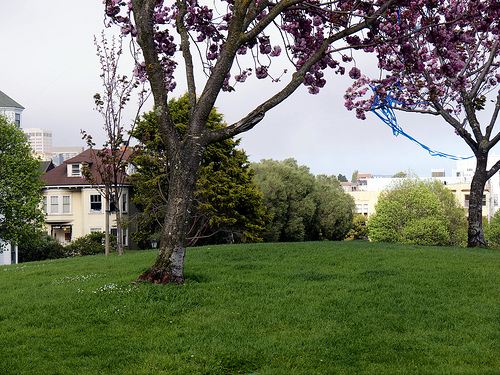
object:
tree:
[113, 86, 277, 248]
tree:
[74, 28, 159, 257]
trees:
[234, 156, 357, 244]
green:
[287, 189, 320, 218]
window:
[88, 193, 104, 215]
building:
[30, 144, 138, 250]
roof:
[39, 142, 138, 188]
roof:
[0, 90, 23, 111]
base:
[129, 255, 195, 286]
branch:
[189, 6, 370, 143]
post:
[113, 209, 128, 257]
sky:
[0, 0, 499, 177]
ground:
[0, 240, 499, 375]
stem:
[145, 161, 202, 270]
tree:
[93, 0, 433, 282]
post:
[100, 196, 109, 257]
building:
[338, 187, 391, 223]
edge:
[341, 189, 355, 239]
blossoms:
[100, 0, 426, 97]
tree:
[342, 0, 499, 247]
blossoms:
[339, 0, 499, 126]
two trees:
[98, 0, 497, 292]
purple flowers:
[341, 66, 395, 123]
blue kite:
[362, 82, 475, 163]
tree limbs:
[370, 105, 436, 116]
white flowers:
[89, 281, 141, 302]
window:
[66, 163, 84, 179]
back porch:
[41, 215, 72, 246]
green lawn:
[0, 242, 499, 374]